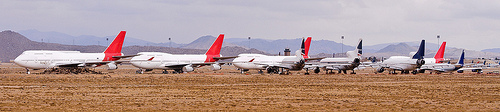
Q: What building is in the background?
A: An air control tower.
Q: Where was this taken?
A: At an airfield.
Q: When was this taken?
A: During the day.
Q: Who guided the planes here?
A: Pilots.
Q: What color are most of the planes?
A: Red and white.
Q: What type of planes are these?
A: Passenger jets.